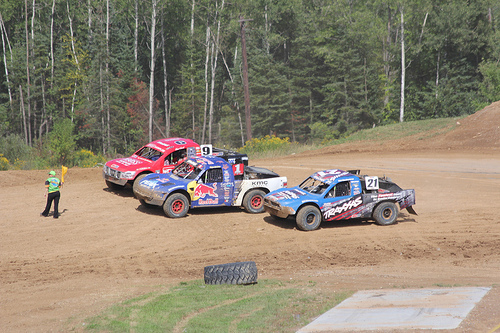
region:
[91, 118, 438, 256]
three race three cars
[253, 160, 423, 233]
race car is color blue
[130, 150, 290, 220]
race car is color purple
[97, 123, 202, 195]
race car is color red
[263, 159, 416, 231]
number of car is 21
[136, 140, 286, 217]
number of car is 9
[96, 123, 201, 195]
number of car is 6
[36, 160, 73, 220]
person with a yellow flag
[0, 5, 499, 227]
trees behind three cars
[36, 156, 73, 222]
person wears green and black pants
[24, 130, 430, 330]
person standing in front of trucks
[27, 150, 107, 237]
person holding yellow flag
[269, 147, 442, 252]
blue truck with white writing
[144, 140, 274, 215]
blue, white, red, and yellow truck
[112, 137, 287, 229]
red rims on truck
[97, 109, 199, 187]
red truck with white writing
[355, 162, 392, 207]
black numbers on white background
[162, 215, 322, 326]
truck tire on grass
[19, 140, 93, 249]
person wearing green and black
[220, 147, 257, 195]
white number on red background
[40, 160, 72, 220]
a woman holding a caution flag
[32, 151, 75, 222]
a woman holding a yellow flag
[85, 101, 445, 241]
three race cars lined up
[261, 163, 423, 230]
a blue and black racing truck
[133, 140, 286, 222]
a blue and white racing truck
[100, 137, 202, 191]
a red racing truck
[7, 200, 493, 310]
a dirt race track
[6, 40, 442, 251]
a race about to start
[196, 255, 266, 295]
an old truck tire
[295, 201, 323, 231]
the front wheel of a truck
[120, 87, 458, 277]
These are old trucks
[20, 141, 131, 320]
This is a man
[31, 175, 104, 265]
The man is wearing green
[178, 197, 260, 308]
This is a large tire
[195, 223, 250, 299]
The tire is made of rubber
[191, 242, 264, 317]
The tire is black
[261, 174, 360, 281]
The truck is blue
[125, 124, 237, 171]
The truck is red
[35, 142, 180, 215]
This is a flag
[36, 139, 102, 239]
The flag is yellow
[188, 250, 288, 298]
large round black tire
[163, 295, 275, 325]
green grass on side of track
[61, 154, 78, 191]
yellow flag in man's hand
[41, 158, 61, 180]
man wearing green cap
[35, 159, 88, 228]
man standing in middle of track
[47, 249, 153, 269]
lines in the dirt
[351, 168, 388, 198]
large white number on side of truck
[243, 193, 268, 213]
red rims on wheel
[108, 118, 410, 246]
trucks lined up to race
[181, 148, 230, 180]
blue top on truck